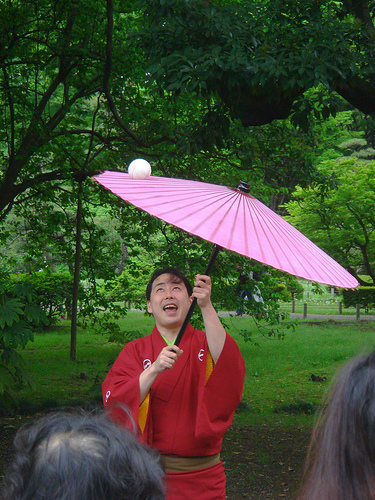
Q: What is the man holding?
A: An umbrella.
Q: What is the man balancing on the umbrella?
A: A ball.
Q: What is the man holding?
A: An umbrella.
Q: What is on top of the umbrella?
A: The ball.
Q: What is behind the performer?
A: Trees.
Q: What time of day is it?
A: Afternoon.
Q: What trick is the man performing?
A: Balancing a ball on an umbrella.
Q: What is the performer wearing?
A: A robe?.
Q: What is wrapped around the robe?
A: A belt.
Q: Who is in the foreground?
A: A man and woman.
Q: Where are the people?
A: A park.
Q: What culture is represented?
A: Asian.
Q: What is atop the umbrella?
A: Baseball.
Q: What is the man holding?
A: Umbrella.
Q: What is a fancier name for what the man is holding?
A: Parasol.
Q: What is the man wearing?
A: Kimono.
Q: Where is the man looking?
A: Upward.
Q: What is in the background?
A: Trees and grass.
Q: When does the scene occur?
A: Daytime.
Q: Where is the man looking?
A: Up at the umbrella.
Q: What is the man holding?
A: An umbrella.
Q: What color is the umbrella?
A: Pink.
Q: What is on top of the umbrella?
A: A baseball.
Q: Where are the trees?
A: Behind the man.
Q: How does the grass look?
A: Very green.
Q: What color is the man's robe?
A: Red.